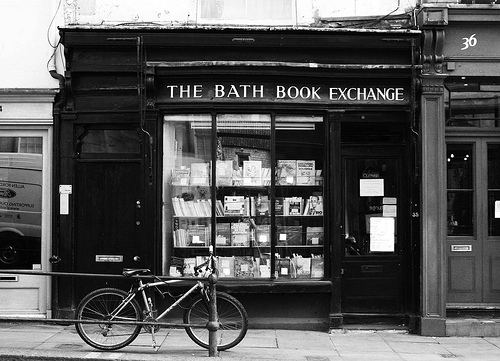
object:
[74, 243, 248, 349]
bike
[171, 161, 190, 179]
books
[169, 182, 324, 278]
shelf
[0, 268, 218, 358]
railing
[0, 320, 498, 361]
sidewalk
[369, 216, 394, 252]
sign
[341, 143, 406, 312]
door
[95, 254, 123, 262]
mailbox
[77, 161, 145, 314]
door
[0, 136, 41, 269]
window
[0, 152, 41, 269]
van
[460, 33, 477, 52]
numbers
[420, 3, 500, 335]
building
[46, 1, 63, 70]
lines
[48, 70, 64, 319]
pipe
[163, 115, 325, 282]
window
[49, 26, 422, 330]
store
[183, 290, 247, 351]
wheel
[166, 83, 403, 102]
words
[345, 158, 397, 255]
windows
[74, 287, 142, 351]
wheels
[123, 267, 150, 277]
seat